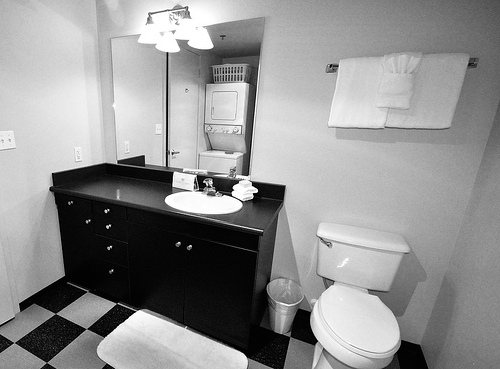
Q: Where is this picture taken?
A: A bathroom.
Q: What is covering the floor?
A: Tile.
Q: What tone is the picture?
A: Black and white.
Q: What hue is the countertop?
A: Black.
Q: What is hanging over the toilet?
A: Towels.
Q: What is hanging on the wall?
A: A mirror.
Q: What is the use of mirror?
A: To reflect.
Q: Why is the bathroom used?
A: To take bath.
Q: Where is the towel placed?
A: N towel bar.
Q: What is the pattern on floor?
A: Checkered.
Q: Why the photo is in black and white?
A: Black shade.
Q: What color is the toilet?
A: White.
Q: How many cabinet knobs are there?
A: 8.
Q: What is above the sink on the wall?
A: Mirror.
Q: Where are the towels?
A: On the towel rack.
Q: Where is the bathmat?
A: On the floor.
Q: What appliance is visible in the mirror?
A: Washer/Dryer.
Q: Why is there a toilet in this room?
A: This is a restroom.